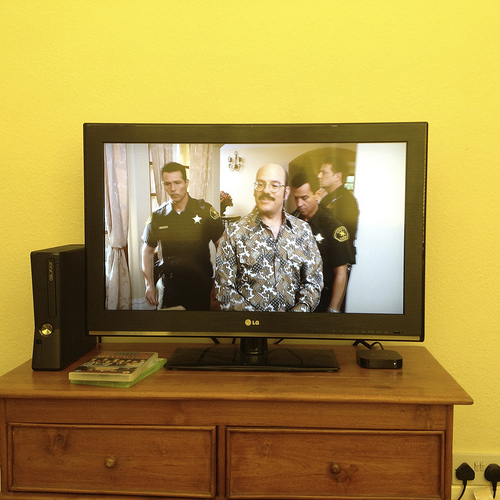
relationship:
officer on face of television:
[140, 159, 230, 310] [80, 119, 430, 377]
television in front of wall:
[80, 119, 430, 377] [2, 3, 494, 499]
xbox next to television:
[27, 244, 101, 373] [80, 119, 430, 377]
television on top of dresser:
[80, 119, 430, 377] [2, 339, 478, 500]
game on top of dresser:
[66, 346, 169, 391] [2, 339, 478, 500]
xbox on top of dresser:
[27, 244, 101, 373] [2, 339, 478, 500]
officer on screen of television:
[140, 159, 230, 310] [80, 119, 430, 377]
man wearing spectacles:
[212, 158, 328, 319] [253, 178, 287, 197]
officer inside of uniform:
[140, 159, 230, 310] [144, 195, 227, 319]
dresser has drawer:
[2, 339, 478, 500] [3, 415, 224, 500]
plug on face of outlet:
[456, 461, 479, 500] [455, 452, 499, 491]